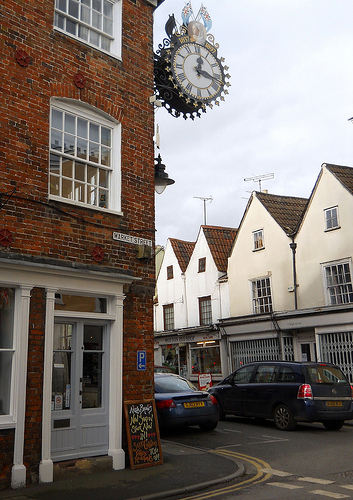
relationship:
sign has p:
[135, 349, 147, 372] [138, 353, 145, 362]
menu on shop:
[125, 401, 161, 462] [0, 0, 163, 483]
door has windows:
[52, 310, 110, 461] [56, 320, 104, 410]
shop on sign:
[2, 1, 158, 483] [135, 349, 147, 372]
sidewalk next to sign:
[2, 438, 240, 499] [135, 349, 147, 372]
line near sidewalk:
[159, 451, 267, 496] [2, 438, 240, 499]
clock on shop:
[151, 33, 228, 123] [0, 0, 163, 483]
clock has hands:
[151, 33, 228, 123] [195, 54, 224, 83]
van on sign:
[206, 361, 353, 432] [135, 349, 147, 372]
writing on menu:
[130, 406, 157, 457] [125, 401, 161, 462]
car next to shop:
[154, 372, 219, 432] [2, 1, 158, 483]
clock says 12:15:
[151, 33, 228, 123] [193, 45, 223, 83]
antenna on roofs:
[241, 171, 274, 190] [227, 193, 306, 257]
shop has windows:
[0, 0, 163, 483] [49, 97, 129, 223]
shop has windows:
[0, 0, 163, 483] [52, 0, 124, 65]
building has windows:
[157, 162, 351, 379] [249, 277, 273, 315]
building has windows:
[157, 162, 351, 379] [197, 299, 212, 326]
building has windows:
[157, 162, 351, 379] [328, 262, 353, 306]